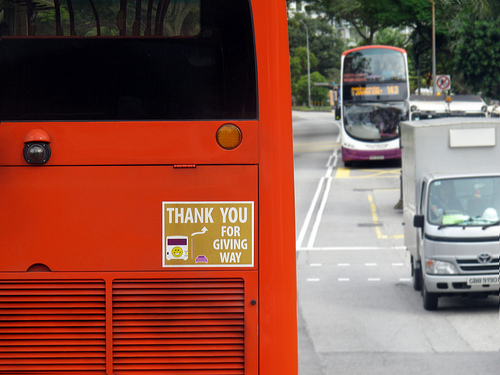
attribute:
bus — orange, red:
[3, 4, 311, 375]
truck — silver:
[389, 109, 499, 310]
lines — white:
[301, 124, 419, 291]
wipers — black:
[426, 211, 499, 232]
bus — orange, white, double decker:
[315, 35, 420, 173]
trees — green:
[292, 0, 499, 111]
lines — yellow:
[333, 165, 413, 243]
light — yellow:
[339, 68, 408, 105]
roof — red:
[336, 41, 415, 60]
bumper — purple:
[334, 141, 409, 170]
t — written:
[160, 199, 177, 229]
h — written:
[169, 200, 184, 229]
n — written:
[193, 202, 205, 227]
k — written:
[203, 198, 217, 225]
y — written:
[217, 202, 231, 225]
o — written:
[227, 202, 237, 227]